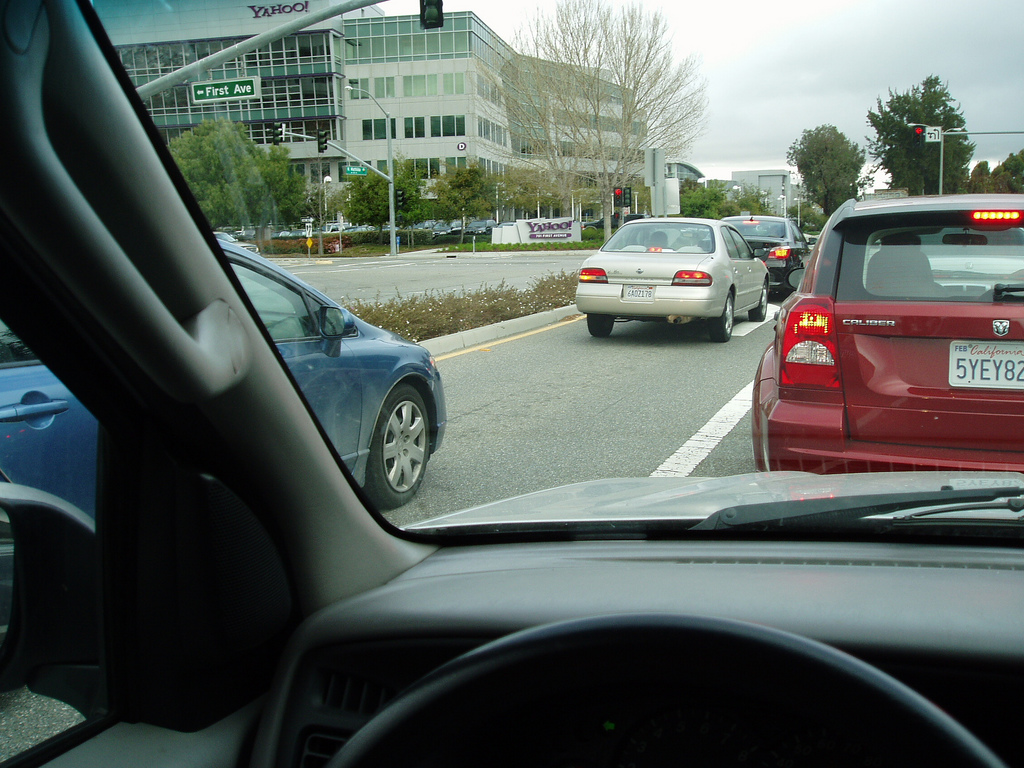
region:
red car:
[775, 157, 1017, 426]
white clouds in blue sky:
[716, 89, 774, 150]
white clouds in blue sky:
[655, 10, 719, 42]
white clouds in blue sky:
[743, 66, 821, 106]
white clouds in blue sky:
[930, 7, 1011, 59]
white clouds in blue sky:
[778, 57, 813, 92]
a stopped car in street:
[569, 218, 772, 342]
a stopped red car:
[753, 187, 1020, 476]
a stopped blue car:
[0, 230, 447, 683]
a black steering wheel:
[305, 612, 1014, 767]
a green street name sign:
[188, 79, 255, 102]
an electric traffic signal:
[314, 126, 330, 152]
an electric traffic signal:
[906, 123, 923, 152]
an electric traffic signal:
[269, 119, 283, 145]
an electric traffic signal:
[611, 186, 622, 206]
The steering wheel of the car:
[593, 621, 743, 647]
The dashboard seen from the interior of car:
[441, 564, 656, 603]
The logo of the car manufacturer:
[995, 317, 1009, 338]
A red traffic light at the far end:
[612, 186, 626, 196]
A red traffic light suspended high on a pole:
[912, 125, 923, 136]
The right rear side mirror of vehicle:
[319, 303, 346, 338]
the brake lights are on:
[566, 136, 801, 408]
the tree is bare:
[460, 7, 714, 189]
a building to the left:
[150, 2, 676, 227]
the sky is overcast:
[605, 20, 983, 158]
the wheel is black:
[361, 364, 450, 521]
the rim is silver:
[367, 384, 444, 503]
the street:
[546, 368, 644, 448]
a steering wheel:
[638, 617, 782, 695]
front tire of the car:
[372, 399, 439, 494]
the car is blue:
[355, 334, 413, 389]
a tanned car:
[576, 215, 757, 345]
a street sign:
[183, 74, 270, 104]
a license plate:
[948, 337, 1023, 395]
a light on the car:
[780, 305, 839, 398]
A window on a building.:
[370, 115, 393, 142]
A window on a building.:
[348, 77, 368, 103]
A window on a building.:
[373, 74, 394, 97]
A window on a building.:
[404, 74, 436, 97]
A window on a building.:
[446, 71, 459, 90]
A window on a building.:
[427, 111, 478, 132]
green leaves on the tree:
[892, 113, 921, 139]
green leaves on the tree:
[918, 98, 944, 153]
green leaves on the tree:
[254, 121, 318, 197]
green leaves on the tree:
[342, 183, 368, 212]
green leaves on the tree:
[444, 159, 499, 220]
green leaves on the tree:
[485, 162, 502, 179]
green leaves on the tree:
[687, 177, 730, 238]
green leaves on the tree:
[778, 148, 813, 218]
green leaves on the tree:
[836, 118, 859, 214]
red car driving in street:
[741, 181, 1020, 480]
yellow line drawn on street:
[431, 313, 583, 371]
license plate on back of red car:
[942, 332, 1022, 393]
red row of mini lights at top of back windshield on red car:
[964, 208, 1022, 232]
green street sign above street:
[177, 75, 263, 111]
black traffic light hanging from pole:
[311, 123, 334, 158]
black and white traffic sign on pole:
[918, 117, 948, 146]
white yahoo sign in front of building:
[484, 208, 587, 254]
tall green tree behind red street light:
[866, 69, 984, 197]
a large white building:
[91, 7, 665, 233]